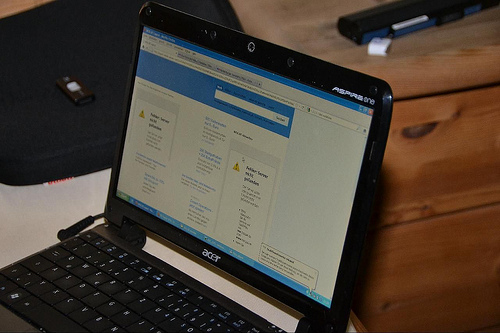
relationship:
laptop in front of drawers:
[23, 32, 418, 331] [242, 15, 497, 331]